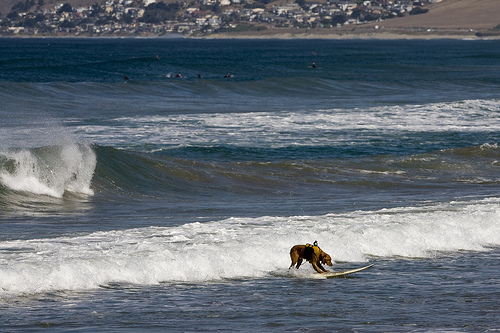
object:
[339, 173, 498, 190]
ripples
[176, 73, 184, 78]
people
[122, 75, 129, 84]
people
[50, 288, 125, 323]
ripples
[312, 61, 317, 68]
surfer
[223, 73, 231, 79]
surfer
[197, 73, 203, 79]
surfer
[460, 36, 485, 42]
rocks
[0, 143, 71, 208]
waves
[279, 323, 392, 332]
ripples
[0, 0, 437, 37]
city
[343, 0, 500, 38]
road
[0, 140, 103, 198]
wave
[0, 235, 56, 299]
wave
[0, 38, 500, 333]
ocean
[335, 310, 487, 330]
ripples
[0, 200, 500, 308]
foam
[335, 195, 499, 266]
wave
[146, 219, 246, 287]
waves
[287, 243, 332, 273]
dog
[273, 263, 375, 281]
surfboard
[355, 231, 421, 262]
waves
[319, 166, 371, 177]
ripples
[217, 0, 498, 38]
land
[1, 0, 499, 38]
distance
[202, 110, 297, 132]
waves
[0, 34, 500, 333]
water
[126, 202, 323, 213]
ripples